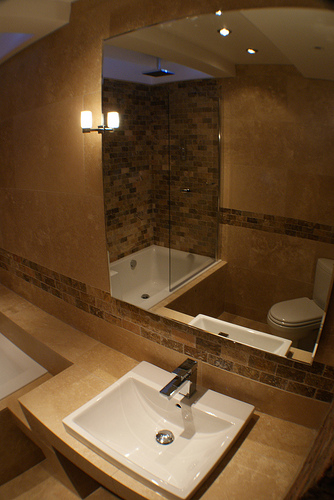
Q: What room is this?
A: Bathroom.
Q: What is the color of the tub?
A: White.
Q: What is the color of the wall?
A: Brown.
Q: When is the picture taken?
A: Night time.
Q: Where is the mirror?
A: Attached to the wall.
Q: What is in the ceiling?
A: Lights.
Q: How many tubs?
A: 1.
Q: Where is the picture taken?
A: In a bathroom.